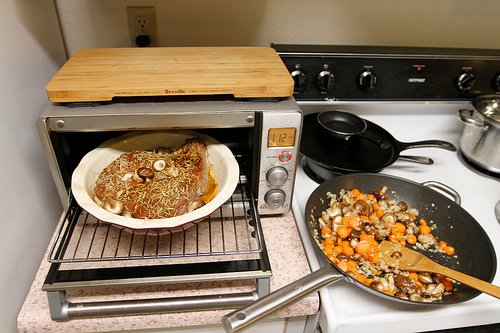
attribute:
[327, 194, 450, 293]
food — cooking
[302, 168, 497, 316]
pan — white, black, silver, large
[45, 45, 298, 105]
cutting board — wooden, brown, thick, wood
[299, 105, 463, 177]
pan — small, cast iron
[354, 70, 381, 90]
knob — black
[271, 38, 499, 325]
stove — white, black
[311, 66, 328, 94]
knob — black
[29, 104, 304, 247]
microwave — silver, stainless steel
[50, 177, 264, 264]
rack — metal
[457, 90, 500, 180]
pot — silver, stainless, large, metal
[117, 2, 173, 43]
outlet — beige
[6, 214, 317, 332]
countertop — cream, beige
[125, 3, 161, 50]
socket — off white, electrical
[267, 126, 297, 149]
display — digital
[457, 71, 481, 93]
knob — black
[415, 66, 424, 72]
light — red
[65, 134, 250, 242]
bowl — round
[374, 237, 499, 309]
spoon — brown, wood, wooden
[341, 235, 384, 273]
carrots — cut